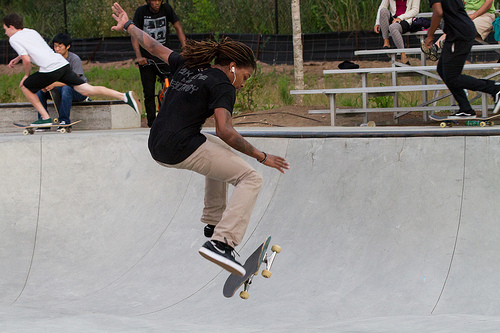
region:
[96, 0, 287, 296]
Skateboarder in a skateboard park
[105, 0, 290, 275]
Young man riding a skateboard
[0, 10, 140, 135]
Skateboarder riding a skateboard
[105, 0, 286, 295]
Skateboarder doing a trick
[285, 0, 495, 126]
Stands for observing skateboarders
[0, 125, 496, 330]
Skateboard trick ramp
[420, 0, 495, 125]
Person riding skateboard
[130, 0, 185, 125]
Guy on bike watching skateboarder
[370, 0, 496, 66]
People watching skateboarders ride and do tricks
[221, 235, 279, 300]
skateboard being ridden by skateboarder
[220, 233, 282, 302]
skateboard with yellow wheels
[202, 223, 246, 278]
pair of black sneakers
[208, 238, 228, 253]
white Nike logo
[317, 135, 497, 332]
curved cement skateboard ramp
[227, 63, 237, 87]
white music headphones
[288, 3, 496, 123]
multi level metal bleechers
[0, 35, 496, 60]
long black fence tarp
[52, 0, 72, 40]
black metal fence spoke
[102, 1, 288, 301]
boy skateboarding on skate ramp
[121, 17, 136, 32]
black and silver wrist watch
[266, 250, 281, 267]
wheel of a skate board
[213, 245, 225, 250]
part of a shoe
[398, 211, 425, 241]
ram of a skating court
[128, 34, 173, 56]
left arm of a skater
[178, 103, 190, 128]
part of a black shirt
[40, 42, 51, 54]
part of a white shirt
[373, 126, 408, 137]
edge of a skating ramp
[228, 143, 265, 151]
right arm of a boy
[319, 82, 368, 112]
edge of a bench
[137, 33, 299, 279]
this is a lady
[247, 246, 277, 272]
this is a skate board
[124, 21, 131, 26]
this is a wrist watch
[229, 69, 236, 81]
this is a earphone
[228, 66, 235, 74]
the earphone is white in color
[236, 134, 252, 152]
this is a tattoo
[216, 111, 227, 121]
the lady is light skinned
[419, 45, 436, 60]
this is a spectacle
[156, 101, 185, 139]
this is a t shirt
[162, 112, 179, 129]
the t shirt is black in color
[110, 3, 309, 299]
boy riding skateboard doing tricks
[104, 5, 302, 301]
boy wearing black shirt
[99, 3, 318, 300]
boy wearing tan pants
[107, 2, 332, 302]
boy wearing black and white sneakers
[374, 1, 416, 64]
girl watching the boys skateboard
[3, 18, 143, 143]
boy wearing white shirt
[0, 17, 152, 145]
boy wearing green shoes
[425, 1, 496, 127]
boy wearing black pants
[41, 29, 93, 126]
boy wearing gray shirt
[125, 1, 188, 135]
boy riding orange bike